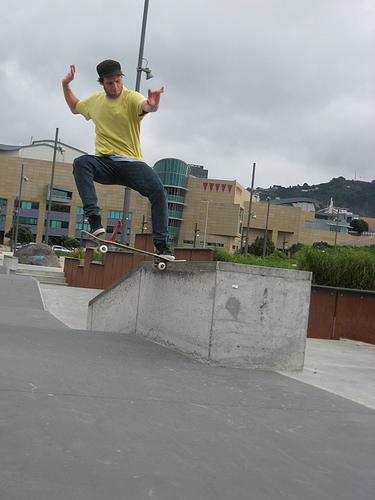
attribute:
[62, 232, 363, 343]
wall — red, brick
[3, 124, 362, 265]
buildings — blue, tan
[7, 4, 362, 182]
sky — grey, cloudy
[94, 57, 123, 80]
cap — man's, brown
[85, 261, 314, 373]
wall — railing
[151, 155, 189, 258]
building — glass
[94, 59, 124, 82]
cap — brown, man's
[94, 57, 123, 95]
head — man's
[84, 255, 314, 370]
block — cement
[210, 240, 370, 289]
shrubbery — green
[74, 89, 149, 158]
shirt — yellow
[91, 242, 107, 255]
wheels — white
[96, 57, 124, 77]
cap — dark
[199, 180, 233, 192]
triangles — red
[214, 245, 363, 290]
bushes — green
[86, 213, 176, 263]
sneakers — black, high top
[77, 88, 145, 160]
tee shirt — yellow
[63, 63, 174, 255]
boy — blue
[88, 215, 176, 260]
high tops — black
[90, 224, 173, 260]
soles — white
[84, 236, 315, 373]
ramp — grey, cement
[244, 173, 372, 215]
hills — green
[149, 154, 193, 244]
center — tall, glass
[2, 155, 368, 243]
building — large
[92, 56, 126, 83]
hat — dark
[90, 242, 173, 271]
wheels — white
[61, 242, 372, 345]
wall — brown, wooden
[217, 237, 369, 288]
vegetation — green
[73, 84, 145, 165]
tee shirt — yellow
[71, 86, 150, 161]
tee shirt — yellow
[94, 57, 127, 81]
hat — black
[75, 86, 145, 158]
t-shirt — man's, yellow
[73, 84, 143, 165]
t-shirt — yellow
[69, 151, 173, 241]
jeans — blue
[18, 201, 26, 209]
window — glass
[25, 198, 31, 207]
window — glass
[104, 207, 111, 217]
window — glass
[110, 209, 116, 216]
window — glass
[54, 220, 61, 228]
window — glass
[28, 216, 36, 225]
window — glass